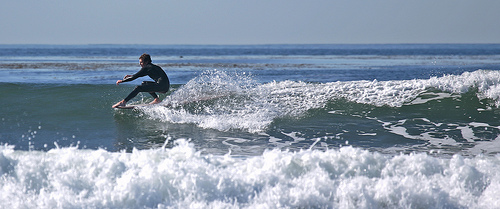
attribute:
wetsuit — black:
[115, 50, 177, 133]